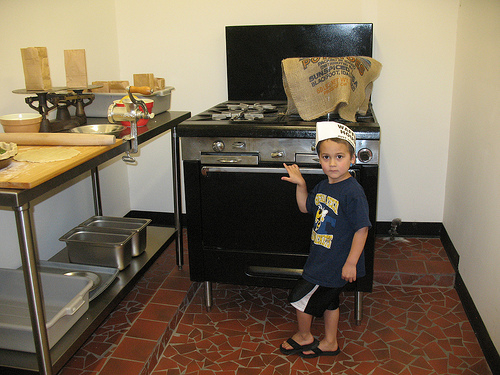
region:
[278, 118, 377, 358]
a casually dressed boy wearing a paper hat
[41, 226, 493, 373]
a red stone mosaic floor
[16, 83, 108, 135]
a metal old fashioned scale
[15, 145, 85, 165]
white dough that has been rolled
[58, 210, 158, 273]
2 metal food bins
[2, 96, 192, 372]
a metal cooking table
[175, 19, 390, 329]
a black gas stove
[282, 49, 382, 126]
a printed burlap sack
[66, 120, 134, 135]
a metal pie pan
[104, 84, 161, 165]
a red mixing bowl and clamp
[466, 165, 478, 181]
part of a wall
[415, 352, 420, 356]
side of a floor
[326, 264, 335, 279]
part of a shirt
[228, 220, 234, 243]
part of an oven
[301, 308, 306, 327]
edge of a leg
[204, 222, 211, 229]
edge of a oven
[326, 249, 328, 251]
part of a shirt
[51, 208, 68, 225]
edge of a table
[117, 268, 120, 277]
side of a bench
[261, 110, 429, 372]
the boy is by the stove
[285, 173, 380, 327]
the boy is wearing striped shorts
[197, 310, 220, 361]
the floor is red tiled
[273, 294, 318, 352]
the boy is wearing flip flops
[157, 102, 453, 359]
the boy is in the kitchen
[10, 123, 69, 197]
dough is on the counter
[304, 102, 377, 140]
the boy is wearing a hat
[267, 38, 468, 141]
a sack is on the stove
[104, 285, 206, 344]
a step is in the kitchen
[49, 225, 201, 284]
steel pans are under the table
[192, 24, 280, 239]
an oven in the kitchen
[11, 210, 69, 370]
the leg of a table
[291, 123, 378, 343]
a boy leaning on the oven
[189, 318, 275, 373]
the tiled floor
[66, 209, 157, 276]
oven dishes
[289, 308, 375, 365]
legs of a boy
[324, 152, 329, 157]
the eye of a boy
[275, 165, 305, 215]
the arm of a boy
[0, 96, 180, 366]
kitchen table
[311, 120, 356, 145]
a chefs cap worn by a boy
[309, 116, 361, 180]
White hat on boy's head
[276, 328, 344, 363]
A pair of black flip flops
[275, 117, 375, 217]
Boy's hand on oven handle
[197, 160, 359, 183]
Handle of an oven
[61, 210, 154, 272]
Silver rectangular pots next to each other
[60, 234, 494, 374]
Brown tiles on the floor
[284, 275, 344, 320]
Black and white shorts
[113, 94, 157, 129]
A bowl is red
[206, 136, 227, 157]
A knob on an oven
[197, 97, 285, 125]
Two burners on a stove